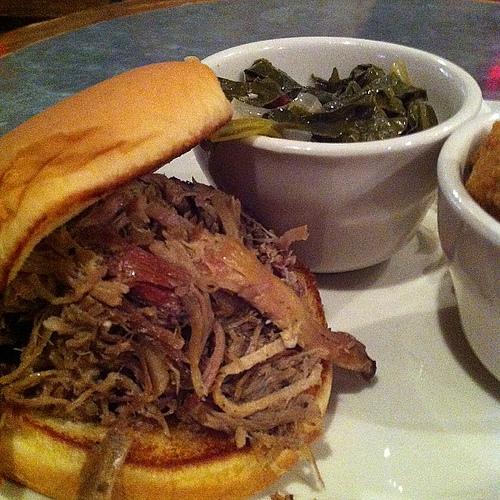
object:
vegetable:
[353, 120, 370, 129]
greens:
[210, 53, 439, 148]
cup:
[176, 35, 483, 275]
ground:
[408, 158, 469, 218]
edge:
[5, 9, 122, 51]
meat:
[72, 411, 134, 497]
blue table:
[0, 4, 500, 131]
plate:
[0, 89, 500, 497]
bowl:
[435, 112, 498, 384]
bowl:
[198, 36, 489, 274]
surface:
[159, 152, 499, 499]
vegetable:
[245, 92, 277, 104]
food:
[0, 43, 499, 500]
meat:
[216, 335, 322, 411]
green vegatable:
[328, 64, 342, 83]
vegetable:
[370, 111, 399, 134]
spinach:
[397, 99, 437, 128]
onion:
[230, 98, 268, 120]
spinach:
[223, 56, 282, 101]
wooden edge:
[1, 0, 208, 62]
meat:
[14, 365, 54, 398]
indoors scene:
[4, 0, 500, 497]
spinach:
[300, 109, 363, 132]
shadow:
[368, 316, 461, 425]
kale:
[265, 89, 326, 123]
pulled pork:
[235, 402, 305, 433]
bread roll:
[0, 54, 374, 500]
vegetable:
[344, 82, 363, 102]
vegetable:
[211, 115, 256, 144]